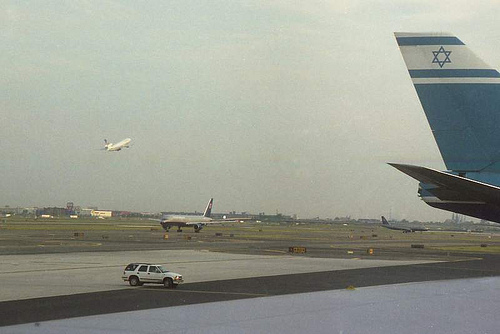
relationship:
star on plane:
[432, 46, 451, 67] [389, 31, 499, 226]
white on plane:
[395, 33, 499, 84] [389, 31, 499, 226]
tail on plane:
[204, 199, 214, 217] [149, 199, 239, 232]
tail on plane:
[104, 138, 111, 148] [101, 138, 133, 151]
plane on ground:
[389, 31, 499, 226] [0, 216, 498, 331]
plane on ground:
[149, 199, 239, 232] [0, 216, 498, 331]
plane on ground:
[381, 216, 429, 234] [0, 216, 498, 331]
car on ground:
[123, 262, 183, 289] [0, 216, 498, 331]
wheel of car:
[129, 277, 138, 285] [123, 262, 183, 289]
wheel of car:
[164, 278, 172, 286] [123, 262, 183, 289]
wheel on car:
[129, 277, 138, 285] [123, 262, 183, 289]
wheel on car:
[164, 278, 172, 286] [123, 262, 183, 289]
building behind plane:
[73, 208, 112, 217] [149, 199, 239, 232]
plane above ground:
[101, 138, 133, 151] [0, 216, 498, 331]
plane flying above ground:
[101, 138, 133, 151] [0, 216, 498, 331]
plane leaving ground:
[101, 138, 133, 151] [0, 216, 498, 331]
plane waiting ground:
[149, 199, 239, 232] [0, 216, 498, 331]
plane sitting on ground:
[149, 199, 239, 232] [0, 216, 498, 331]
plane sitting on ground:
[381, 216, 429, 234] [0, 216, 498, 331]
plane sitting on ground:
[389, 31, 499, 226] [0, 216, 498, 331]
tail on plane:
[389, 31, 499, 226] [389, 31, 499, 226]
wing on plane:
[195, 219, 249, 224] [149, 199, 239, 232]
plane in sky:
[101, 138, 133, 151] [0, 1, 495, 225]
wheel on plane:
[162, 226, 202, 232] [149, 199, 239, 232]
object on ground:
[347, 249, 352, 253] [0, 216, 498, 331]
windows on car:
[124, 266, 169, 272] [123, 262, 183, 289]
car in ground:
[123, 262, 183, 289] [0, 216, 498, 331]